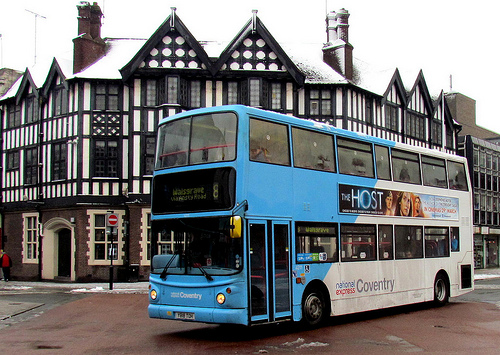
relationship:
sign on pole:
[101, 206, 127, 241] [110, 235, 117, 294]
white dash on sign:
[100, 217, 129, 223] [101, 206, 127, 241]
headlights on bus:
[150, 275, 249, 324] [154, 107, 474, 310]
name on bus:
[336, 278, 421, 303] [154, 107, 474, 310]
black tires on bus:
[300, 281, 330, 331] [154, 107, 474, 310]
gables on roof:
[145, 25, 289, 87] [9, 23, 459, 126]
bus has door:
[154, 107, 474, 310] [248, 216, 292, 315]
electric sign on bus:
[159, 178, 224, 211] [154, 107, 474, 310]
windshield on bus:
[149, 228, 244, 276] [154, 107, 474, 310]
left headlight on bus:
[142, 282, 168, 314] [154, 107, 474, 310]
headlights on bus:
[215, 292, 226, 305] [154, 107, 474, 310]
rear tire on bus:
[437, 270, 460, 305] [154, 107, 474, 310]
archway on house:
[38, 217, 76, 298] [7, 5, 494, 309]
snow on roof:
[109, 44, 130, 89] [9, 23, 459, 126]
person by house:
[3, 229, 32, 288] [7, 5, 494, 309]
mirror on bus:
[230, 206, 248, 245] [154, 107, 474, 310]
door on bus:
[248, 216, 292, 315] [154, 107, 474, 310]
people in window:
[293, 132, 331, 174] [252, 122, 288, 167]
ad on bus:
[328, 168, 469, 234] [154, 107, 474, 310]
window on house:
[49, 84, 72, 116] [7, 5, 494, 309]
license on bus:
[163, 304, 217, 339] [154, 107, 474, 310]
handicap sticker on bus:
[303, 260, 313, 282] [154, 107, 474, 310]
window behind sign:
[49, 84, 72, 116] [101, 206, 127, 241]